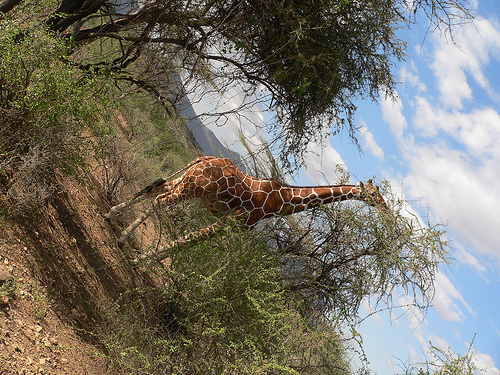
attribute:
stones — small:
[0, 240, 81, 340]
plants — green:
[223, 275, 321, 356]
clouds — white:
[377, 129, 487, 246]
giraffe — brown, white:
[139, 126, 413, 300]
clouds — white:
[361, 117, 464, 210]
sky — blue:
[378, 17, 490, 337]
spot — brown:
[262, 189, 282, 216]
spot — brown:
[213, 189, 236, 201]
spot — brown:
[280, 180, 296, 204]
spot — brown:
[212, 175, 231, 195]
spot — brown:
[314, 186, 332, 204]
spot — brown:
[265, 186, 283, 220]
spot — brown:
[247, 191, 271, 207]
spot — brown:
[340, 186, 353, 196]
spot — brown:
[191, 171, 209, 188]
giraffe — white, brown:
[109, 161, 402, 251]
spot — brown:
[275, 182, 294, 207]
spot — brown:
[217, 180, 227, 193]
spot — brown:
[176, 175, 192, 193]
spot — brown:
[247, 208, 263, 224]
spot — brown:
[220, 189, 231, 204]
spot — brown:
[303, 180, 332, 199]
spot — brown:
[302, 185, 316, 202]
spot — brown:
[289, 186, 301, 198]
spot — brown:
[262, 193, 282, 218]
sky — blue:
[164, 0, 491, 373]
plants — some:
[210, 223, 384, 371]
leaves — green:
[214, 266, 285, 354]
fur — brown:
[218, 174, 272, 223]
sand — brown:
[16, 214, 89, 362]